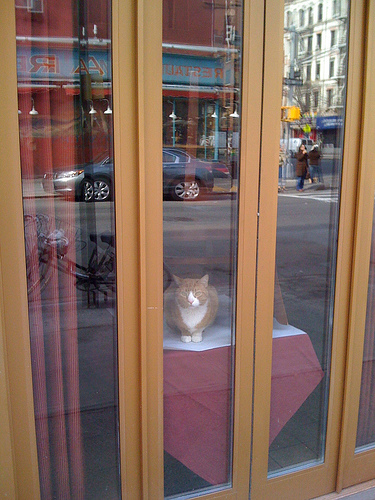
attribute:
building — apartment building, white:
[279, 1, 347, 122]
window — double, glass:
[69, 79, 355, 390]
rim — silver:
[173, 179, 200, 201]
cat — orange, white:
[160, 265, 217, 352]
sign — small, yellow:
[282, 103, 302, 121]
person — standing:
[302, 138, 320, 173]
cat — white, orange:
[163, 270, 220, 345]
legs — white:
[180, 327, 203, 342]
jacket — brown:
[293, 148, 307, 174]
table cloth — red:
[163, 335, 324, 483]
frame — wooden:
[0, 0, 374, 499]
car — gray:
[41, 144, 232, 201]